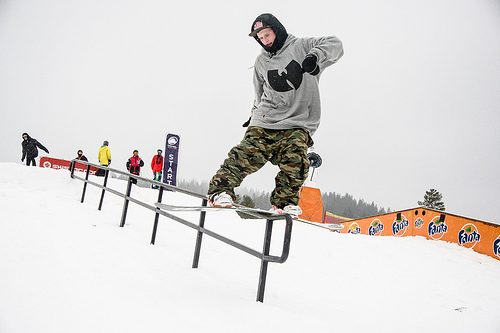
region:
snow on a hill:
[438, 240, 489, 264]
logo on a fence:
[448, 221, 485, 250]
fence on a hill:
[365, 200, 482, 256]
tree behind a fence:
[406, 180, 455, 220]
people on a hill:
[97, 142, 183, 210]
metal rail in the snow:
[199, 218, 306, 319]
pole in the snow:
[243, 219, 278, 313]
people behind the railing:
[83, 137, 185, 196]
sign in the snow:
[150, 120, 192, 199]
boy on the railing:
[200, 10, 335, 240]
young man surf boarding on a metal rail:
[207, 10, 352, 221]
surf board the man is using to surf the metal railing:
[149, 194, 300, 217]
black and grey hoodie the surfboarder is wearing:
[225, 32, 344, 132]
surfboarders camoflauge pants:
[207, 118, 313, 204]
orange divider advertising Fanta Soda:
[331, 203, 498, 258]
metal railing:
[61, 148, 294, 308]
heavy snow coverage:
[7, 162, 423, 319]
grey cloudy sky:
[51, 35, 199, 110]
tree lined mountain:
[247, 188, 387, 222]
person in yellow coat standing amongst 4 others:
[96, 136, 112, 168]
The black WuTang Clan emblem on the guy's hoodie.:
[264, 66, 314, 90]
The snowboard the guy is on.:
[154, 192, 304, 216]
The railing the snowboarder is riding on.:
[68, 158, 304, 303]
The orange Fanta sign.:
[336, 201, 498, 270]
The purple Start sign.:
[159, 135, 186, 192]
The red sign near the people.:
[36, 152, 113, 177]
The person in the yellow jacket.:
[97, 134, 114, 172]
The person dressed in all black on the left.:
[12, 127, 49, 164]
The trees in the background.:
[157, 158, 401, 218]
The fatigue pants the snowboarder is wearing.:
[214, 130, 314, 200]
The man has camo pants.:
[235, 12, 324, 237]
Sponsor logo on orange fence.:
[427, 205, 490, 266]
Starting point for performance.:
[160, 128, 191, 197]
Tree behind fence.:
[416, 177, 450, 229]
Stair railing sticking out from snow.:
[68, 153, 163, 233]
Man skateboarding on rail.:
[233, 19, 325, 253]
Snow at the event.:
[37, 155, 71, 190]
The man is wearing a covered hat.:
[237, 7, 300, 59]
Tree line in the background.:
[324, 176, 366, 221]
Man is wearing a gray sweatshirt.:
[239, 20, 346, 135]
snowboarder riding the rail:
[129, 4, 354, 234]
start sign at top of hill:
[140, 112, 206, 198]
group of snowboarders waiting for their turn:
[13, 101, 200, 180]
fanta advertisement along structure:
[287, 182, 496, 252]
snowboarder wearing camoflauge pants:
[170, 103, 342, 225]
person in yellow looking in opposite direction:
[82, 124, 123, 190]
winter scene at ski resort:
[10, 7, 450, 306]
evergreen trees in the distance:
[230, 167, 468, 224]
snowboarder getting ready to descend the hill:
[19, 104, 66, 182]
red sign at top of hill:
[27, 120, 111, 180]